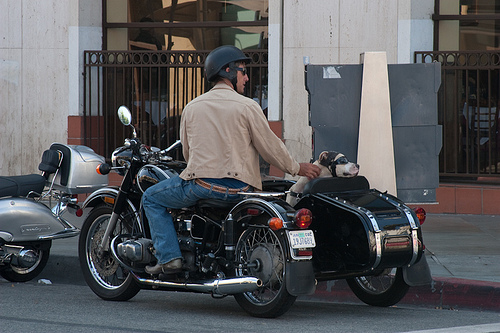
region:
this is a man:
[166, 40, 279, 186]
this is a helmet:
[208, 44, 235, 66]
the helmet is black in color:
[207, 49, 228, 59]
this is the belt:
[204, 180, 236, 193]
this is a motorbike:
[219, 211, 327, 311]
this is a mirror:
[117, 103, 137, 127]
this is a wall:
[293, 10, 412, 42]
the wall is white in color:
[294, 14, 332, 35]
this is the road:
[15, 287, 63, 327]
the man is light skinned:
[304, 160, 321, 175]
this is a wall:
[8, 27, 63, 119]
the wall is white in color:
[3, 25, 61, 107]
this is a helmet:
[200, 41, 252, 71]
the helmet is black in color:
[213, 50, 234, 62]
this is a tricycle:
[71, 104, 436, 319]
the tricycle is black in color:
[319, 213, 346, 250]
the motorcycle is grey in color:
[73, 164, 88, 186]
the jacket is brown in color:
[201, 107, 237, 158]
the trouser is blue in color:
[156, 220, 174, 250]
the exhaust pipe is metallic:
[221, 277, 257, 287]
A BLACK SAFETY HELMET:
[174, 43, 263, 93]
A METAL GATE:
[41, 46, 283, 152]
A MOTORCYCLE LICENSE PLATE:
[274, 224, 329, 255]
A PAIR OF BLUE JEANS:
[137, 171, 249, 277]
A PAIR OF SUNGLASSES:
[229, 60, 256, 80]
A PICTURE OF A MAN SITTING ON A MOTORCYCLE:
[72, 40, 322, 320]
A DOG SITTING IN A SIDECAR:
[273, 146, 442, 300]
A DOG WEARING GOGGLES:
[280, 146, 364, 211]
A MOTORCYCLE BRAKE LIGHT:
[288, 204, 326, 238]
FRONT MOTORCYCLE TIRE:
[75, 203, 152, 304]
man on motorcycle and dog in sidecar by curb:
[60, 30, 460, 305]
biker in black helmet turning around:
[160, 32, 320, 214]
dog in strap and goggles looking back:
[295, 126, 361, 196]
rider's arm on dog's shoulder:
[215, 51, 365, 216]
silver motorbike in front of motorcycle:
[5, 130, 155, 285]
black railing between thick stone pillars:
[10, 1, 490, 166]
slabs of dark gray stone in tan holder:
[300, 45, 462, 210]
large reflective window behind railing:
[68, 0, 285, 142]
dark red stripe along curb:
[281, 250, 496, 316]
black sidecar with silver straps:
[297, 160, 432, 285]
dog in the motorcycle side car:
[285, 123, 378, 219]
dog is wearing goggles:
[319, 130, 376, 192]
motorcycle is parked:
[62, 70, 444, 330]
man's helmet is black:
[183, 37, 258, 92]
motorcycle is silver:
[3, 200, 78, 245]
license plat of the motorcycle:
[280, 221, 333, 256]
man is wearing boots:
[133, 249, 190, 277]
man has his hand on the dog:
[271, 146, 361, 221]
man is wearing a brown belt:
[178, 173, 288, 216]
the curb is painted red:
[430, 267, 498, 310]